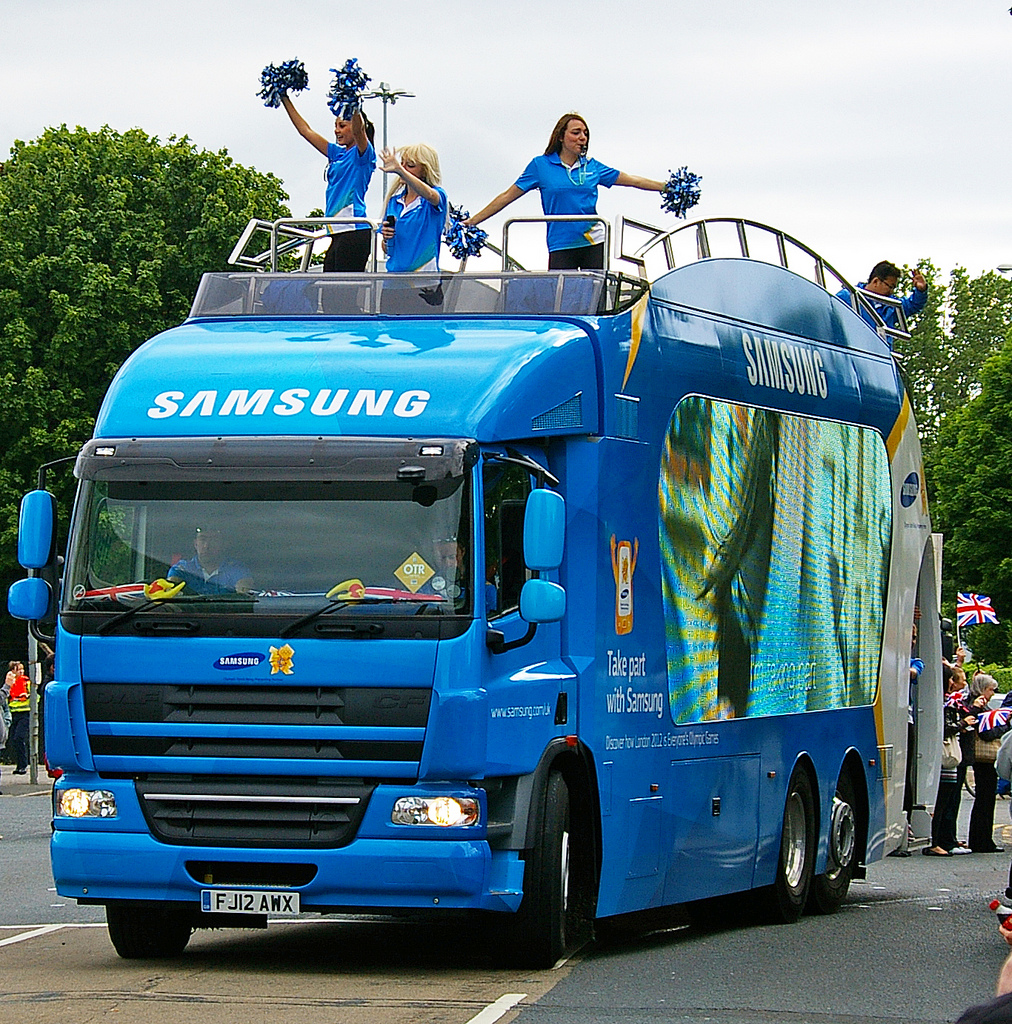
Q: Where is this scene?
A: On a samsung company tour bus.